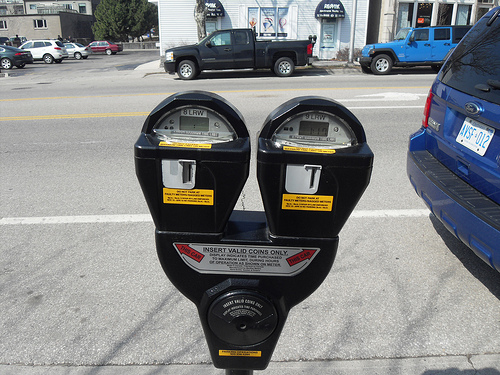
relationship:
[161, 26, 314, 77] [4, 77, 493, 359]
truck across street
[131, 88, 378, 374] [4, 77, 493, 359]
meter at street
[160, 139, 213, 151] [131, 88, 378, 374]
sticker top of meter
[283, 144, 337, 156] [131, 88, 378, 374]
sticker top of meter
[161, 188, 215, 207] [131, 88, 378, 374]
sticker bottom of meter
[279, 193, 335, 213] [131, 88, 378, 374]
sticker bottom of meter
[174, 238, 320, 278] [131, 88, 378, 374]
sticker center of meter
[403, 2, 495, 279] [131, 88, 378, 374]
ford near meter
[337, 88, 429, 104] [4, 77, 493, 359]
arrow on road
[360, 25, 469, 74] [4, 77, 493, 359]
car across street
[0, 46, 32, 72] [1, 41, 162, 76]
car in lot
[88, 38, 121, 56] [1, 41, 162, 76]
car in lot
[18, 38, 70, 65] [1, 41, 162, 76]
car in lot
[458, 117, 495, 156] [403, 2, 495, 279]
plate on ford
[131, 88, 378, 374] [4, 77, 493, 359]
meter by street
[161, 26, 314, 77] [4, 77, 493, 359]
truck by street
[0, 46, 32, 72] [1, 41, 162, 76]
vehicle in lot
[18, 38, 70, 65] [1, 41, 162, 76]
vehicle in lot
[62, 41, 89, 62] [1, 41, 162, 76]
vehicle in lot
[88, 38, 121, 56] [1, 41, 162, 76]
vehicle in lot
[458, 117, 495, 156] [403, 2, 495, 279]
tag on vehicle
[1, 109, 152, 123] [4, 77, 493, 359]
line on street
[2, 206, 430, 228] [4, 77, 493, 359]
line on street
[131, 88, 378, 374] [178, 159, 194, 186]
meter has slot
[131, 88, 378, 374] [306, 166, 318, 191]
meter has slot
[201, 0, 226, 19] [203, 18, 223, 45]
awning over door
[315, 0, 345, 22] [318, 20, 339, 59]
awning over door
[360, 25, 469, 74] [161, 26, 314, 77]
jeep behind truck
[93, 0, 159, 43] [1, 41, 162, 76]
tree behind lot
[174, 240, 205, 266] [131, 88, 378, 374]
arrow on meter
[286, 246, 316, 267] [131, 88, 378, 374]
arrow on meter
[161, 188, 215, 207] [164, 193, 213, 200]
sticker with writing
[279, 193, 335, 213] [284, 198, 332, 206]
sticker with writing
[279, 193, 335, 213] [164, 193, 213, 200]
sticker with writing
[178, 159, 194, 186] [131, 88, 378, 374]
slot on meter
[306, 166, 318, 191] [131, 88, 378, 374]
slot on meter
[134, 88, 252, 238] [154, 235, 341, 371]
meter on stand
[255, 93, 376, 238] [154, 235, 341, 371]
meter on stand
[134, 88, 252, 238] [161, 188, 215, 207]
meter has sticker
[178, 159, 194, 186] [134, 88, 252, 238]
slot on meter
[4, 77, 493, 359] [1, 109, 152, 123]
street has line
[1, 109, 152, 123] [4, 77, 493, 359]
line middle of street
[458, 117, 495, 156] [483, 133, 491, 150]
tag has number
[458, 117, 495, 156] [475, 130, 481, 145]
tag has number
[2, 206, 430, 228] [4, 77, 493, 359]
line in street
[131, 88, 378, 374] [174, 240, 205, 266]
meter has arrow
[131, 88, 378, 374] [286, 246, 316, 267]
meter has arrow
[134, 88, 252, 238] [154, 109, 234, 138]
meter has face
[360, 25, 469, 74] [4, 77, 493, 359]
jeep on street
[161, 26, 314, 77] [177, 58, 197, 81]
truck has tire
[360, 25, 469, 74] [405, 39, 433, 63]
jeep has door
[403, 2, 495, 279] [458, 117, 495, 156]
truck has plate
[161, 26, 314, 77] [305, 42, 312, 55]
truck has light